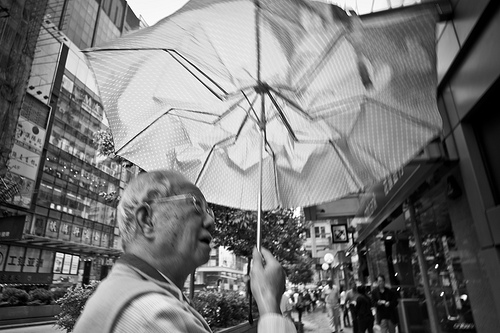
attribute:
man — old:
[104, 161, 237, 331]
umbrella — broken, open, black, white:
[119, 44, 415, 177]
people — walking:
[311, 271, 405, 331]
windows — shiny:
[50, 144, 127, 252]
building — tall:
[17, 14, 154, 280]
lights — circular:
[318, 249, 349, 277]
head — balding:
[153, 156, 200, 195]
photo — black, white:
[36, 15, 489, 318]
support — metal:
[221, 91, 309, 189]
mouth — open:
[199, 232, 218, 249]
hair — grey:
[120, 175, 182, 195]